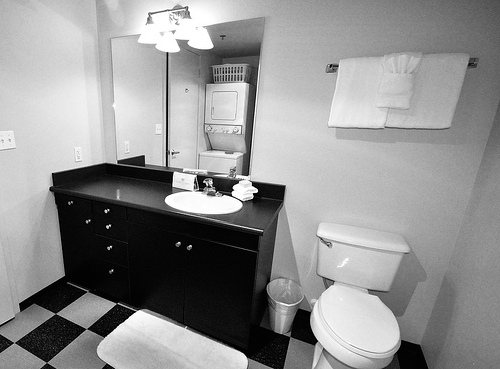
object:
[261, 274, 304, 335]
can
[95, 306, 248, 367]
rug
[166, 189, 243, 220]
sink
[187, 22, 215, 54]
light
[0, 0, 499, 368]
bathroom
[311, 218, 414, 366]
toilet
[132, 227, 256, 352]
cabinet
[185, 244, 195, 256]
handle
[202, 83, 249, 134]
dryer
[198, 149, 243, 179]
washer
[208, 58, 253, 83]
basket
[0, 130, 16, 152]
switch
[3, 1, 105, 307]
wall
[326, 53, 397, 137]
towel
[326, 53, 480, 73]
rack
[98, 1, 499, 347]
wall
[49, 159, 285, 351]
vanity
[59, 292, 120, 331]
floor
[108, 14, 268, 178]
mirror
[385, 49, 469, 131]
towel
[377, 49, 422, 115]
towel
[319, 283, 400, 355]
lid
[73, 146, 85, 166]
outlet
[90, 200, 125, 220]
drawer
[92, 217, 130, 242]
drawer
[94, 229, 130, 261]
drawer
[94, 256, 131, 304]
drawer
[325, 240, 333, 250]
handle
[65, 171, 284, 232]
countertop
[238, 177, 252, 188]
soap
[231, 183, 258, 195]
washcloth